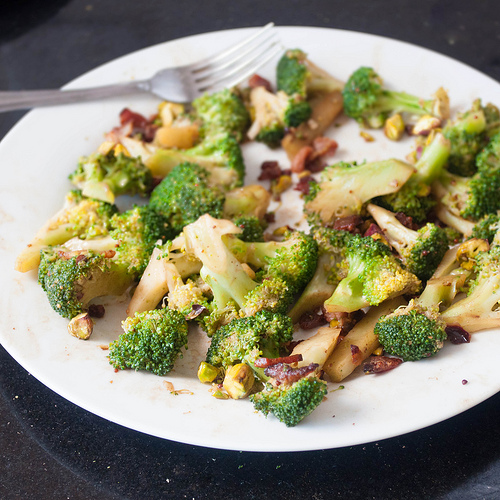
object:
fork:
[0, 21, 286, 114]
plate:
[0, 25, 500, 454]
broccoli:
[147, 161, 227, 234]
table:
[0, 0, 499, 499]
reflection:
[0, 364, 499, 500]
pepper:
[121, 107, 143, 127]